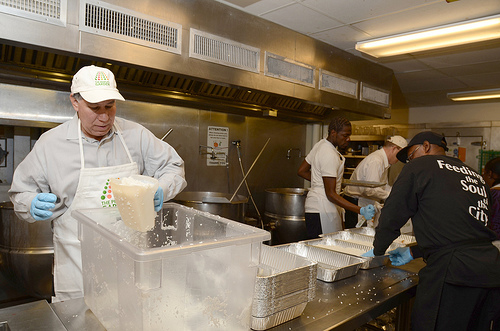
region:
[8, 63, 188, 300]
A man working in a commercial kitchen.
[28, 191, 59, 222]
A blue vinyl glove worn by the kitchen employee.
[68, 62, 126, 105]
A white hat with a logo on the front.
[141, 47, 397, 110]
Ventilators above the stoves in the kitchen.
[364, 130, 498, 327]
An worker dressed in black.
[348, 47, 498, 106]
Fluorescent lights in the ceiling.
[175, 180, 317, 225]
Large metal pots on the stove.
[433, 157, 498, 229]
The white lettering on the back of an employee.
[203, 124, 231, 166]
A warning sign on the wall.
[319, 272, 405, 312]
Food crumbs on the table.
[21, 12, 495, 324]
People working in a kitchen.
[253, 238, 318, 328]
A stack of aluminum pans.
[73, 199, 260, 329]
A large plastic container.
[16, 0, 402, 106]
Silver vents on the wall.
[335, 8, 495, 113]
Lights on the ceiling.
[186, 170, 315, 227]
Large silver cooking containers.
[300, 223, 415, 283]
Aluminum pans lined up on table.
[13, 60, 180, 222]
Man on left wearing blue gloves.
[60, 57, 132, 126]
A white hat.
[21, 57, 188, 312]
Man wearing a white apron.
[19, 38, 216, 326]
CHEF PREPARING BATTER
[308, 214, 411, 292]
PANS FULL OF BATTER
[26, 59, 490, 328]
VOLUNTEERS HELPING IN FOOD BANK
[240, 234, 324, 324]
EMPTY FOIL PANS WAITING TO BE FILLED WITH BATTER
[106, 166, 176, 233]
FLOUR FOR BATTER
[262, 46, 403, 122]
VENTS OVER FOOD PREPARATION AREA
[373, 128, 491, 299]
MAN WEARING FEEDING THE SOUL OF THE CITY TEE SHIRT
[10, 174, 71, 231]
BLUE RUBBER GLOVES BEING USED TO PREPARE FOOD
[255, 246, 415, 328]
FOOD PREPARATION TABLE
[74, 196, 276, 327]
LARGE CONTAINER USED TO PREPARE BATTER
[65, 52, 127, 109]
white baseball cap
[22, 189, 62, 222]
blue gloves on a worker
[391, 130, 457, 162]
black baseball cap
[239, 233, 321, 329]
stack of silver cooking trays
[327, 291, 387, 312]
crumbs spilled on a counter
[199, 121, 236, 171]
sign on a stainless steel wall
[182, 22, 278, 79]
white ceiling grate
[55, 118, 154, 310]
white apron with a logo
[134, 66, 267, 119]
silver oven range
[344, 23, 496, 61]
flourescent lights on the celing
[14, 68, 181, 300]
a man shaking a pitcher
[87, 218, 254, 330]
a clear tub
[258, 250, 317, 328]
a stack of metal pans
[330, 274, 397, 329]
a stain less steel table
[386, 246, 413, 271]
a blue gloved hand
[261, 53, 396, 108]
a roll of vents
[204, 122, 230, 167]
a paper on the wall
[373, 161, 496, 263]
a black shirt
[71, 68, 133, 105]
a white ball cap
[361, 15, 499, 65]
a white ceiling light